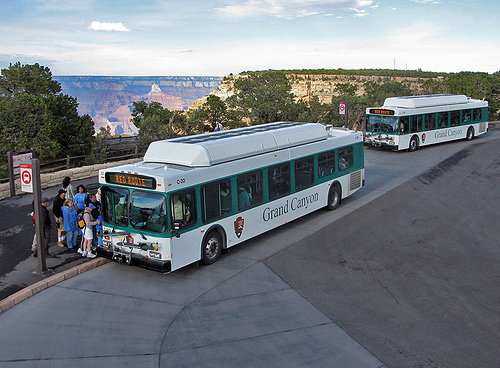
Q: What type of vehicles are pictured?
A: Buses.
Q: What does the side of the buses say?
A: Grand canyon.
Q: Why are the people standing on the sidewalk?
A: They are waiting to get on the bus.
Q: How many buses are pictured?
A: Two.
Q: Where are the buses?
A: At the bus stops.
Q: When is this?
A: Daytime.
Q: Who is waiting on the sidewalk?
A: The passengers.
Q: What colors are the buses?
A: White and green.